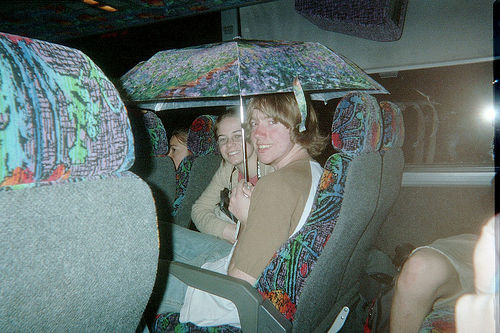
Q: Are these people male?
A: No, they are both male and female.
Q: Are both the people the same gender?
A: No, they are both male and female.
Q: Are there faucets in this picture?
A: No, there are no faucets.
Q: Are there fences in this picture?
A: No, there are no fences.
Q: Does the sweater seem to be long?
A: Yes, the sweater is long.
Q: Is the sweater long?
A: Yes, the sweater is long.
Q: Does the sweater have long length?
A: Yes, the sweater is long.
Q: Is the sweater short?
A: No, the sweater is long.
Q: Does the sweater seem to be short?
A: No, the sweater is long.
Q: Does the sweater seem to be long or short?
A: The sweater is long.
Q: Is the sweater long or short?
A: The sweater is long.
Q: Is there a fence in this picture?
A: No, there are no fences.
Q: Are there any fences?
A: No, there are no fences.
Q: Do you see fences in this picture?
A: No, there are no fences.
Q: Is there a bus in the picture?
A: Yes, there is a bus.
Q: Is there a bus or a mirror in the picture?
A: Yes, there is a bus.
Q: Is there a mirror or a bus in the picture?
A: Yes, there is a bus.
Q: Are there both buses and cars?
A: No, there is a bus but no cars.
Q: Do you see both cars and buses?
A: No, there is a bus but no cars.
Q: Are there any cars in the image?
A: No, there are no cars.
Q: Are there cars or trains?
A: No, there are no cars or trains.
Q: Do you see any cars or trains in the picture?
A: No, there are no cars or trains.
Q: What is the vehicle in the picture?
A: The vehicle is a bus.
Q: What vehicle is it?
A: The vehicle is a bus.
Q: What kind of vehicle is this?
A: This is a bus.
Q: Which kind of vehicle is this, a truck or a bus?
A: This is a bus.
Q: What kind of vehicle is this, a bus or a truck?
A: This is a bus.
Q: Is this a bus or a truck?
A: This is a bus.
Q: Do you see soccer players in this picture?
A: No, there are no soccer players.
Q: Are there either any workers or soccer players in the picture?
A: No, there are no soccer players or workers.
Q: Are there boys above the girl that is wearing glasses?
A: Yes, there is a boy above the girl.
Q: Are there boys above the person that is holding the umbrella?
A: Yes, there is a boy above the girl.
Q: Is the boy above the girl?
A: Yes, the boy is above the girl.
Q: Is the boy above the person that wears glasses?
A: Yes, the boy is above the girl.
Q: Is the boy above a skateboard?
A: No, the boy is above the girl.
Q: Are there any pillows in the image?
A: No, there are no pillows.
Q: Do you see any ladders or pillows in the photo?
A: No, there are no pillows or ladders.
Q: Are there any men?
A: No, there are no men.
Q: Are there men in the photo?
A: No, there are no men.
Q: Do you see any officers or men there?
A: No, there are no men or officers.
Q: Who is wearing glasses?
A: The girl is wearing glasses.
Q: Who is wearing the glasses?
A: The girl is wearing glasses.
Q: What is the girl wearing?
A: The girl is wearing glasses.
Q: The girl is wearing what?
A: The girl is wearing glasses.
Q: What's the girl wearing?
A: The girl is wearing glasses.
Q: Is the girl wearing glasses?
A: Yes, the girl is wearing glasses.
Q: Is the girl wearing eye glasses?
A: No, the girl is wearing glasses.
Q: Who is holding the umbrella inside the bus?
A: The girl is holding the umbrella.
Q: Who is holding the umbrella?
A: The girl is holding the umbrella.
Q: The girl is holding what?
A: The girl is holding the umbrella.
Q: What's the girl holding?
A: The girl is holding the umbrella.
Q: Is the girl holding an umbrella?
A: Yes, the girl is holding an umbrella.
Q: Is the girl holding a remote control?
A: No, the girl is holding an umbrella.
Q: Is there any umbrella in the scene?
A: Yes, there is an umbrella.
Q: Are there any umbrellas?
A: Yes, there is an umbrella.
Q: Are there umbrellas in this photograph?
A: Yes, there is an umbrella.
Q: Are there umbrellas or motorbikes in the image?
A: Yes, there is an umbrella.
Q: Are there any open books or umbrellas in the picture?
A: Yes, there is an open umbrella.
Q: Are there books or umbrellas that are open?
A: Yes, the umbrella is open.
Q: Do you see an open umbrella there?
A: Yes, there is an open umbrella.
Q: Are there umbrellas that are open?
A: Yes, there is an umbrella that is open.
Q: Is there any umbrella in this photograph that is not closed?
A: Yes, there is a open umbrella.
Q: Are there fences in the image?
A: No, there are no fences.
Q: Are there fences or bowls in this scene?
A: No, there are no fences or bowls.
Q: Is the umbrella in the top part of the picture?
A: Yes, the umbrella is in the top of the image.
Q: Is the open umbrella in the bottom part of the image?
A: No, the umbrella is in the top of the image.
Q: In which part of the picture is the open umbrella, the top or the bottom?
A: The umbrella is in the top of the image.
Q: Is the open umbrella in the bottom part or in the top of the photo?
A: The umbrella is in the top of the image.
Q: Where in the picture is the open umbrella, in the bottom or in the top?
A: The umbrella is in the top of the image.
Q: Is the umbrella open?
A: Yes, the umbrella is open.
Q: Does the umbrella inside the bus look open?
A: Yes, the umbrella is open.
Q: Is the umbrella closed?
A: No, the umbrella is open.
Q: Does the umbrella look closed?
A: No, the umbrella is open.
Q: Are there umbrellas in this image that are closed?
A: No, there is an umbrella but it is open.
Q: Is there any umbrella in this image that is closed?
A: No, there is an umbrella but it is open.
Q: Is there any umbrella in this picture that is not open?
A: No, there is an umbrella but it is open.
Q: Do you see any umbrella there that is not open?
A: No, there is an umbrella but it is open.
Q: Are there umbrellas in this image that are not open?
A: No, there is an umbrella but it is open.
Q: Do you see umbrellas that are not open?
A: No, there is an umbrella but it is open.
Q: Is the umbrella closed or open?
A: The umbrella is open.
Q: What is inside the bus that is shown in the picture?
A: The umbrella is inside the bus.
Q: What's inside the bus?
A: The umbrella is inside the bus.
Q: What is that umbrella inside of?
A: The umbrella is inside the bus.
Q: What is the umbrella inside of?
A: The umbrella is inside the bus.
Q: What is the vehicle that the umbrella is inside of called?
A: The vehicle is a bus.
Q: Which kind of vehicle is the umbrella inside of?
A: The umbrella is inside the bus.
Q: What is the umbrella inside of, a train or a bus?
A: The umbrella is inside a bus.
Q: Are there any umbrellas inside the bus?
A: Yes, there is an umbrella inside the bus.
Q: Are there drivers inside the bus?
A: No, there is an umbrella inside the bus.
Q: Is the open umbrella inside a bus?
A: Yes, the umbrella is inside a bus.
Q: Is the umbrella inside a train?
A: No, the umbrella is inside a bus.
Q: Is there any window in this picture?
A: Yes, there is a window.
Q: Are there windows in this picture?
A: Yes, there is a window.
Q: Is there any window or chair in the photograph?
A: Yes, there is a window.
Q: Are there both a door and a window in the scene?
A: No, there is a window but no doors.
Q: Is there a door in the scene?
A: No, there are no doors.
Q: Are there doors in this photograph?
A: No, there are no doors.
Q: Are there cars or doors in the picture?
A: No, there are no doors or cars.